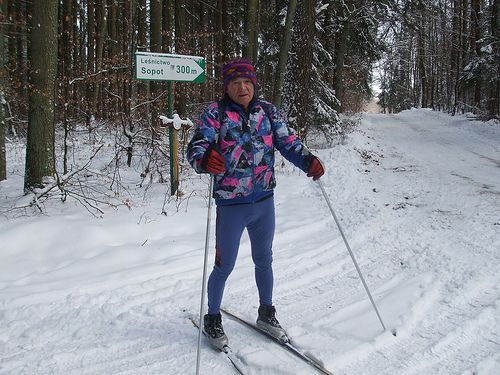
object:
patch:
[58, 124, 144, 199]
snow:
[0, 105, 496, 373]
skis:
[183, 307, 330, 374]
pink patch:
[265, 169, 272, 183]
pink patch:
[220, 175, 240, 187]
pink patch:
[205, 116, 221, 129]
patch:
[217, 135, 238, 155]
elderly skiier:
[185, 57, 398, 375]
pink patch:
[233, 146, 242, 161]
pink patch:
[224, 111, 239, 123]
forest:
[3, 2, 499, 215]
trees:
[24, 0, 58, 197]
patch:
[261, 134, 272, 147]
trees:
[263, 2, 494, 114]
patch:
[281, 135, 297, 148]